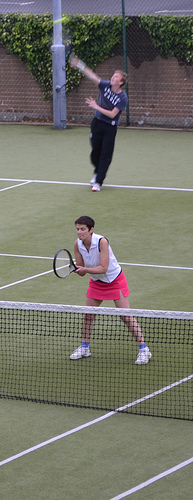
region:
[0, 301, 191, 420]
The net on the tennis court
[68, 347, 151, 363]
The woman is wearing white shoes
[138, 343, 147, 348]
A blue sock on the woman's right foot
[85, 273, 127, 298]
The woman is wearing a pink skirt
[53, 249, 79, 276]
A black tennis racket in the woman's hands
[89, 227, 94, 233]
The left ear of the woman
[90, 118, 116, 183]
The man is wearing black pants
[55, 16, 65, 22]
A yellow tennis ball in the air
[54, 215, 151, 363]
A woman standing by the net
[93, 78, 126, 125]
The man is wearing a blue shirt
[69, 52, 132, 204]
a man standing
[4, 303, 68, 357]
a net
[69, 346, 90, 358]
white shoes the women is wearing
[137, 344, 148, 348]
women is wearing white socks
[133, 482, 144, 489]
white lines on the tennis court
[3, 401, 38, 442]
the tennis court is green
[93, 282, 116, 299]
a pink skirt the women is wearing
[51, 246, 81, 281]
a tennis racket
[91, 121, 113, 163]
the man is wearing black pants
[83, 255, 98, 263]
the women is wearing a white shirt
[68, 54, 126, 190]
Man serving the ball in tennis match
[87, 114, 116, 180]
Black pants on man tennis player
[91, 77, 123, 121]
Blue shirt with white design on man tennis player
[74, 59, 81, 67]
White wristband on man tennis player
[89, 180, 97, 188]
White shoe on man tennis player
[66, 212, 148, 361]
Lady player standing at net in a tennis match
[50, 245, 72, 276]
Black tennis racket held by lady player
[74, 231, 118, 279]
White top worn by lady tennis player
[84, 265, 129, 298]
Hot pink tennis skirt worn by player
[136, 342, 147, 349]
Blue sock on lady tennis player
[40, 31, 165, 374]
people are playing tennis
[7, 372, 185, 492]
white lines in a tennis court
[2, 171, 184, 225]
white lines in a tennis court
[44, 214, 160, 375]
woman wears a red skirt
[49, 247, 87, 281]
the racket is black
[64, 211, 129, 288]
woman has a white top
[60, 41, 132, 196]
tennis player wears black pants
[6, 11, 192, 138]
there is a brick wall behind the tennis court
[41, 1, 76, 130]
gray pole inside the tennis court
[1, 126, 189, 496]
tennis court is color green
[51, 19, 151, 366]
two people playing tennis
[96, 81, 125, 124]
the t-shirt is blue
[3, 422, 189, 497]
a couple of white lines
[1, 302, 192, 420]
the tennis mesh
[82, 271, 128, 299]
a red mini skirt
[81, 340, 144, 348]
a pair of blue socks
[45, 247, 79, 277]
a black tennis racket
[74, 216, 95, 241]
the woman short black hair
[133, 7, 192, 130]
a metal mesh in the background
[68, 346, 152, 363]
a couple of white sneakers